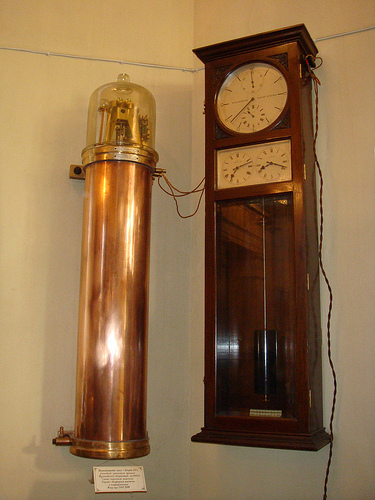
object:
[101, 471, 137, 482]
letters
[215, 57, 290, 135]
time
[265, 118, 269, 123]
black line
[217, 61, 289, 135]
device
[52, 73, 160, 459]
barometer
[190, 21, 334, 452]
clock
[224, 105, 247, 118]
line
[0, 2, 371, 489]
wall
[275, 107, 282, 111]
roman numeral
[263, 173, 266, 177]
vii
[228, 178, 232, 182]
vii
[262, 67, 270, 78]
line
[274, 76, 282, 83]
black line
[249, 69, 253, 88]
line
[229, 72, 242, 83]
line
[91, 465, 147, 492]
card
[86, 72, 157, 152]
glass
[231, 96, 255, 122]
hand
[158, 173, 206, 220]
wire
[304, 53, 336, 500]
wire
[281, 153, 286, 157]
numeral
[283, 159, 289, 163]
numeral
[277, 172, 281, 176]
numeral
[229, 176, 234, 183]
numeral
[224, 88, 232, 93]
numeral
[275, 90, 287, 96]
line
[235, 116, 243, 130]
line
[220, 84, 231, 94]
line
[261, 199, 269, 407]
pendule